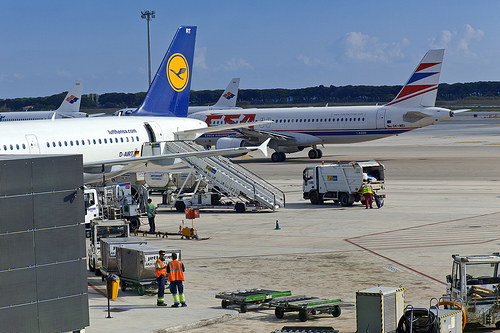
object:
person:
[165, 252, 189, 308]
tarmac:
[89, 115, 498, 332]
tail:
[382, 47, 456, 139]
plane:
[188, 46, 476, 166]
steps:
[163, 138, 288, 215]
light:
[138, 9, 157, 20]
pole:
[146, 16, 153, 87]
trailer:
[213, 286, 292, 314]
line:
[344, 239, 452, 289]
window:
[360, 117, 367, 122]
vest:
[361, 182, 374, 194]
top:
[166, 260, 187, 282]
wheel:
[270, 151, 287, 163]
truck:
[301, 158, 390, 209]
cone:
[272, 217, 282, 232]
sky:
[2, 1, 498, 101]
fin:
[129, 24, 200, 119]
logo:
[165, 50, 191, 93]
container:
[115, 242, 184, 281]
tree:
[316, 85, 329, 101]